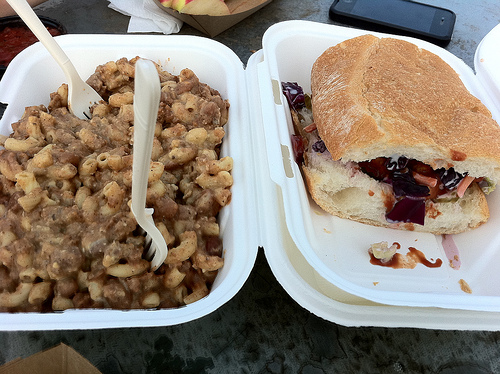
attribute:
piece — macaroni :
[38, 104, 128, 188]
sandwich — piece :
[313, 62, 479, 234]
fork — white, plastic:
[118, 52, 168, 277]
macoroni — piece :
[1, 52, 231, 309]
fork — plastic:
[119, 41, 181, 274]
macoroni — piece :
[5, 132, 37, 159]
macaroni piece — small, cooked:
[1, 272, 36, 309]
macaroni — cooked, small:
[6, 47, 252, 334]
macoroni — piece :
[22, 273, 55, 310]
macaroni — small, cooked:
[3, 131, 31, 153]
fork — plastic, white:
[20, 12, 82, 75]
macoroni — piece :
[2, 277, 30, 310]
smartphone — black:
[329, 0, 456, 47]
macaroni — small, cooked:
[36, 112, 182, 212]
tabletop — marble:
[2, 2, 499, 371]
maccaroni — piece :
[68, 212, 82, 243]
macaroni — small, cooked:
[164, 231, 199, 264]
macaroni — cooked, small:
[195, 170, 231, 187]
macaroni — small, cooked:
[35, 182, 146, 254]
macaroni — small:
[6, 168, 48, 216]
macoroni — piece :
[10, 95, 132, 310]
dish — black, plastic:
[0, 12, 67, 71]